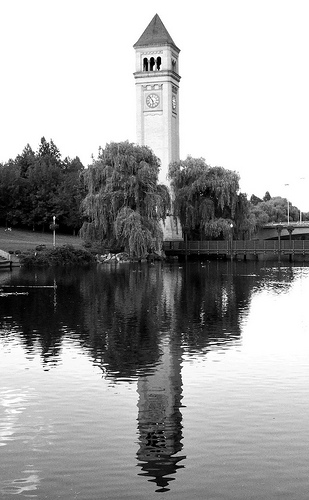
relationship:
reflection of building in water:
[115, 317, 202, 496] [196, 345, 234, 398]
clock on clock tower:
[144, 92, 162, 113] [126, 6, 193, 242]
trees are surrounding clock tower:
[90, 138, 162, 248] [126, 6, 193, 242]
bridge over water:
[260, 217, 309, 238] [196, 345, 234, 398]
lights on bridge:
[283, 198, 306, 217] [260, 217, 309, 238]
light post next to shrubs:
[43, 211, 67, 247] [7, 186, 41, 235]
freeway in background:
[265, 221, 309, 227] [259, 182, 292, 196]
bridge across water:
[260, 217, 309, 238] [196, 345, 234, 398]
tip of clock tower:
[148, 10, 164, 23] [126, 6, 193, 242]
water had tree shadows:
[196, 345, 234, 398] [198, 259, 261, 338]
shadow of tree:
[51, 299, 100, 346] [185, 162, 245, 240]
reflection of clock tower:
[115, 317, 202, 496] [126, 6, 193, 242]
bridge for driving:
[260, 217, 309, 238] [293, 214, 303, 226]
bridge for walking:
[260, 217, 309, 238] [269, 224, 282, 233]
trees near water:
[90, 138, 162, 248] [196, 345, 234, 398]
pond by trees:
[22, 423, 79, 500] [90, 138, 162, 248]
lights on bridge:
[283, 198, 294, 212] [172, 239, 308, 253]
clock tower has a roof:
[126, 6, 193, 242] [135, 7, 183, 49]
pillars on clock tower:
[141, 53, 163, 72] [126, 6, 193, 242]